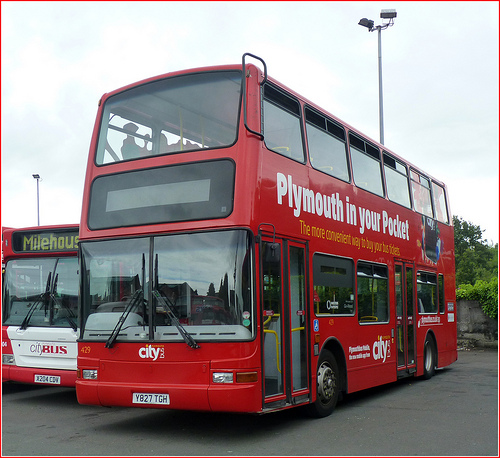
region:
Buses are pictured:
[16, 29, 485, 454]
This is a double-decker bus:
[66, 60, 472, 414]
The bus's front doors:
[251, 222, 321, 409]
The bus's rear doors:
[386, 252, 423, 379]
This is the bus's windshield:
[75, 227, 257, 353]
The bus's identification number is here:
[74, 342, 98, 359]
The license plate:
[126, 388, 176, 410]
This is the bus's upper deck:
[84, 51, 477, 222]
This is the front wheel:
[315, 334, 350, 419]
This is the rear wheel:
[417, 325, 443, 382]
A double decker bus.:
[69, 61, 464, 411]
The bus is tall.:
[67, 65, 469, 429]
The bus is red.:
[65, 67, 457, 418]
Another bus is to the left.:
[0, 213, 107, 395]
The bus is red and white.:
[5, 218, 101, 393]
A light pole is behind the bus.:
[346, 5, 408, 155]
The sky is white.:
[20, 10, 189, 57]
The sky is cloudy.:
[21, 4, 201, 59]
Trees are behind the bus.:
[441, 204, 499, 315]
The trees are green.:
[443, 217, 497, 298]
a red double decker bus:
[72, 57, 463, 427]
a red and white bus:
[3, 222, 79, 390]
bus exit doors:
[252, 229, 312, 406]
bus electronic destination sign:
[10, 229, 80, 251]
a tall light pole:
[350, 4, 409, 154]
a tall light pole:
[25, 168, 45, 222]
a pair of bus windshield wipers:
[103, 285, 200, 350]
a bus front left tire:
[307, 338, 346, 413]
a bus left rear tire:
[420, 332, 436, 378]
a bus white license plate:
[128, 390, 170, 406]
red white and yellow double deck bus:
[91, 63, 458, 398]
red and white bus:
[7, 230, 71, 377]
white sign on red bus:
[133, 345, 171, 364]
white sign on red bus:
[274, 174, 347, 223]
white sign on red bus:
[342, 199, 409, 236]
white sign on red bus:
[354, 339, 391, 359]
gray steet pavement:
[405, 381, 464, 436]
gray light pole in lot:
[360, 2, 413, 130]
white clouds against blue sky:
[23, 14, 316, 52]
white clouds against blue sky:
[406, 25, 473, 154]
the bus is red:
[72, 74, 319, 362]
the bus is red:
[66, 43, 431, 439]